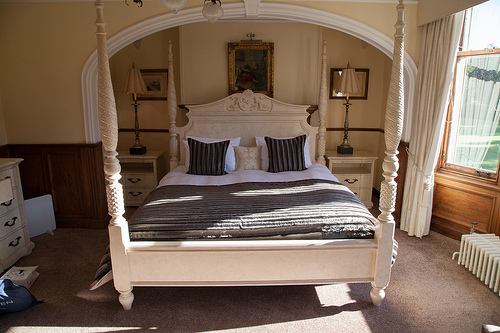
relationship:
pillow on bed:
[264, 132, 306, 173] [93, 0, 409, 310]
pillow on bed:
[186, 139, 231, 171] [93, 0, 409, 310]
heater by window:
[450, 222, 499, 300] [441, 0, 499, 176]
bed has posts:
[95, 10, 402, 296] [385, 1, 415, 292]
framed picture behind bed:
[227, 32, 277, 98] [65, 4, 455, 314]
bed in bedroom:
[93, 0, 409, 310] [6, 4, 484, 299]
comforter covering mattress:
[92, 163, 392, 293] [134, 163, 373, 235]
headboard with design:
[175, 85, 322, 168] [214, 89, 290, 117]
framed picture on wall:
[227, 32, 277, 98] [145, 34, 347, 97]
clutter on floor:
[1, 263, 44, 315] [0, 205, 498, 329]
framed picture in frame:
[227, 32, 277, 98] [214, 31, 294, 108]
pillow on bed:
[230, 143, 263, 177] [109, 91, 401, 324]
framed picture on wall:
[227, 32, 277, 98] [145, 16, 362, 121]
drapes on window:
[414, 10, 456, 232] [464, 14, 498, 174]